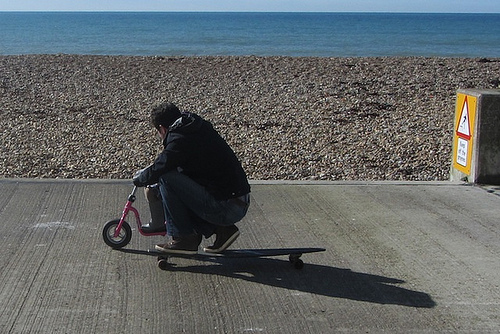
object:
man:
[133, 103, 252, 254]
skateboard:
[144, 247, 325, 270]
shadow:
[176, 252, 438, 309]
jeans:
[158, 172, 252, 238]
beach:
[0, 54, 499, 183]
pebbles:
[268, 128, 276, 135]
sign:
[449, 92, 476, 175]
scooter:
[103, 180, 167, 249]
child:
[140, 182, 163, 235]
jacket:
[132, 112, 250, 199]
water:
[0, 12, 498, 58]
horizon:
[1, 8, 498, 16]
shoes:
[154, 238, 203, 256]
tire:
[103, 219, 132, 251]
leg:
[138, 183, 166, 232]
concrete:
[1, 178, 499, 333]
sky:
[1, 0, 499, 14]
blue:
[0, 1, 499, 58]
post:
[449, 90, 499, 182]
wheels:
[158, 259, 307, 271]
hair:
[150, 102, 179, 127]